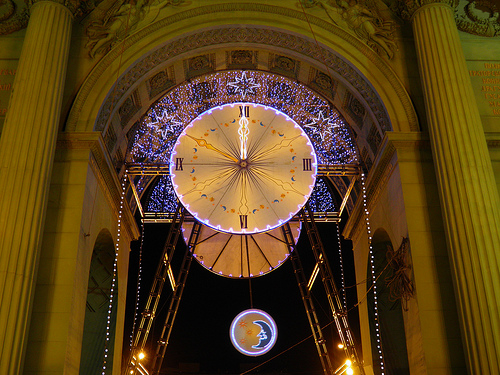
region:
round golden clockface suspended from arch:
[170, 98, 322, 236]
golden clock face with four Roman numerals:
[172, 104, 321, 230]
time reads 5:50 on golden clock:
[173, 91, 319, 238]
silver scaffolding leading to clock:
[123, 208, 215, 373]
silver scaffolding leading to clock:
[285, 204, 370, 374]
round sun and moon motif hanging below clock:
[228, 307, 280, 362]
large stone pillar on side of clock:
[4, 0, 96, 372]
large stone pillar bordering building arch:
[412, 0, 499, 369]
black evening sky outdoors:
[125, 218, 358, 368]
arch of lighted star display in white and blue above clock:
[125, 69, 360, 168]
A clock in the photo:
[187, 136, 307, 207]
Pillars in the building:
[390, 114, 444, 266]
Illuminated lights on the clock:
[181, 102, 318, 232]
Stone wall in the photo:
[405, 178, 451, 294]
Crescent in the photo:
[255, 321, 280, 351]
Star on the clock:
[232, 73, 260, 104]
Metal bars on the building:
[145, 261, 183, 326]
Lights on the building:
[341, 177, 388, 268]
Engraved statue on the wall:
[80, 5, 210, 66]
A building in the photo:
[398, 158, 490, 315]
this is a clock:
[103, 34, 335, 259]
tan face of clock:
[165, 88, 326, 247]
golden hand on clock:
[185, 120, 226, 167]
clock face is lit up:
[172, 100, 316, 248]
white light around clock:
[150, 99, 332, 244]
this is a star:
[132, 87, 190, 149]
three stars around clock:
[125, 61, 380, 170]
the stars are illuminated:
[106, 54, 380, 193]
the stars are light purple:
[120, 44, 367, 181]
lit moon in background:
[218, 285, 283, 372]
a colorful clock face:
[172, 96, 319, 226]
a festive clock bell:
[232, 306, 275, 355]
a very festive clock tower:
[102, 77, 379, 370]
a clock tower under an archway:
[48, 18, 449, 363]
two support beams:
[281, 211, 361, 370]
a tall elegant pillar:
[409, 4, 497, 374]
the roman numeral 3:
[298, 156, 313, 171]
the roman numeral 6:
[239, 213, 249, 233]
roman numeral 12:
[237, 104, 255, 121]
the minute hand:
[184, 128, 236, 166]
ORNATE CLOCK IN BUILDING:
[163, 100, 323, 238]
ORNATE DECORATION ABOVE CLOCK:
[298, 94, 353, 151]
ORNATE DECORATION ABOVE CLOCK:
[203, 75, 265, 95]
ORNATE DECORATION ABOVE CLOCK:
[146, 113, 175, 142]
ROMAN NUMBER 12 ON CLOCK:
[229, 101, 254, 125]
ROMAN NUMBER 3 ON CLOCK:
[293, 150, 319, 177]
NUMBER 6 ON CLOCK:
[230, 210, 257, 230]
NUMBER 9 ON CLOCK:
[172, 155, 190, 175]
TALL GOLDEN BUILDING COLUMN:
[4, 81, 56, 187]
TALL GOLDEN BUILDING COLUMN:
[441, 151, 482, 228]